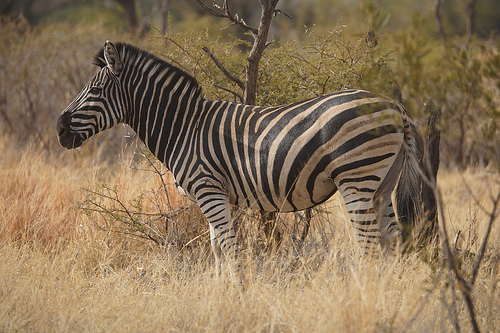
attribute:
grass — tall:
[114, 213, 386, 329]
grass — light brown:
[47, 179, 247, 324]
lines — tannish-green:
[330, 113, 386, 153]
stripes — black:
[312, 99, 393, 219]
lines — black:
[192, 184, 226, 231]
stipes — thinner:
[243, 162, 317, 229]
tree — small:
[281, 2, 475, 134]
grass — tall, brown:
[39, 170, 191, 310]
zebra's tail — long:
[399, 117, 455, 244]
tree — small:
[205, 4, 301, 118]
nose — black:
[50, 104, 77, 135]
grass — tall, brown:
[17, 201, 87, 301]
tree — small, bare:
[204, 3, 281, 100]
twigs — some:
[403, 141, 498, 327]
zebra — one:
[51, 35, 447, 258]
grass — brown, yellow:
[73, 270, 248, 324]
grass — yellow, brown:
[21, 169, 105, 294]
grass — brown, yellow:
[169, 257, 359, 319]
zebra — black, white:
[49, 40, 436, 272]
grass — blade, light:
[58, 136, 84, 180]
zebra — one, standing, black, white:
[46, 33, 454, 290]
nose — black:
[43, 114, 81, 160]